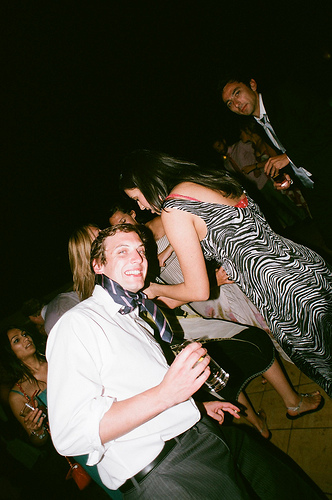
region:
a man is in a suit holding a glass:
[210, 65, 330, 207]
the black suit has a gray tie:
[247, 80, 330, 217]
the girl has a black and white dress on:
[120, 154, 331, 364]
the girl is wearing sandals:
[246, 389, 325, 441]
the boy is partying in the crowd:
[46, 216, 226, 488]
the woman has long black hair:
[111, 145, 246, 216]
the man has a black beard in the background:
[199, 128, 237, 167]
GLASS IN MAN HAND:
[207, 371, 216, 388]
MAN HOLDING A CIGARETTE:
[230, 403, 242, 417]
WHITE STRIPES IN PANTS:
[185, 472, 197, 494]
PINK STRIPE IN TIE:
[124, 298, 131, 302]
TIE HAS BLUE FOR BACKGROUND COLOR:
[114, 296, 119, 300]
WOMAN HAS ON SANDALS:
[290, 395, 313, 415]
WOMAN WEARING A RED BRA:
[238, 199, 247, 206]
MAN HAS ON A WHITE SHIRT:
[127, 362, 141, 382]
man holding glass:
[169, 338, 233, 392]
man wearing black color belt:
[110, 434, 184, 492]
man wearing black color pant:
[155, 432, 330, 498]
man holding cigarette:
[222, 402, 243, 424]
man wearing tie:
[97, 278, 185, 340]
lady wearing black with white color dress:
[228, 211, 329, 334]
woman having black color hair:
[116, 151, 233, 197]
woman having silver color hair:
[62, 231, 92, 292]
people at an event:
[7, 74, 325, 494]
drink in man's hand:
[173, 337, 236, 397]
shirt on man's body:
[42, 288, 193, 457]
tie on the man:
[252, 119, 317, 187]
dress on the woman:
[221, 201, 317, 385]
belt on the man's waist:
[117, 441, 169, 472]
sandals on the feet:
[253, 397, 324, 430]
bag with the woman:
[55, 467, 102, 492]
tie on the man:
[222, 157, 261, 183]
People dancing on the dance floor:
[5, 144, 325, 498]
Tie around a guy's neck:
[88, 266, 176, 348]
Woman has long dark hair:
[108, 143, 245, 216]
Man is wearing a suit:
[214, 71, 329, 196]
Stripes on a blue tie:
[88, 271, 176, 346]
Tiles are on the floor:
[227, 354, 330, 498]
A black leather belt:
[113, 424, 188, 496]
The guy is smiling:
[84, 222, 151, 295]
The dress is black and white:
[159, 194, 329, 397]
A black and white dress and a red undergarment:
[163, 181, 331, 395]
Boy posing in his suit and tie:
[44, 226, 319, 486]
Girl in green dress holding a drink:
[4, 325, 85, 498]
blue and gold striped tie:
[94, 274, 173, 344]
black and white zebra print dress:
[162, 198, 330, 387]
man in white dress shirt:
[45, 224, 213, 491]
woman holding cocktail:
[4, 325, 47, 434]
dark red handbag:
[62, 460, 93, 493]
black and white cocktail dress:
[158, 194, 330, 397]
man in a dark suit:
[217, 77, 330, 181]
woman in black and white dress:
[119, 147, 331, 391]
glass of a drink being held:
[169, 336, 235, 401]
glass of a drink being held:
[162, 330, 240, 399]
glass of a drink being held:
[164, 334, 240, 404]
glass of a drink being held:
[169, 333, 239, 401]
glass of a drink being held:
[163, 326, 235, 399]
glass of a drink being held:
[170, 333, 235, 397]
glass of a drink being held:
[169, 333, 242, 409]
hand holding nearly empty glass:
[170, 339, 229, 395]